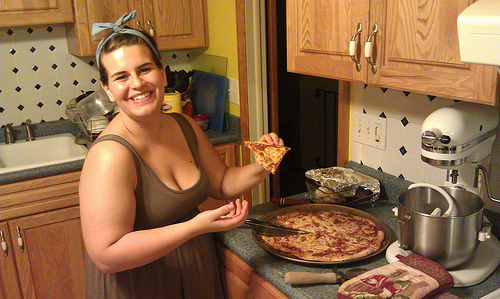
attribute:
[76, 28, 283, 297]
woman — caucasian, smiling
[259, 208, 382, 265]
pizza — cheese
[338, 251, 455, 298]
mitt — decorative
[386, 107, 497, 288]
mixer — chrome, silver, white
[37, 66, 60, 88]
tile — black, ceramic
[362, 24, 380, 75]
handle — white, silver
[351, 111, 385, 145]
outlet — white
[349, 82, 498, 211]
wall — white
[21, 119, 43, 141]
fuacet — silver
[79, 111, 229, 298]
dress — brown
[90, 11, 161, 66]
headband — grey, blue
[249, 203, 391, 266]
pan — round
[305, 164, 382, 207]
foil — tin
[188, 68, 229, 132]
board — cutting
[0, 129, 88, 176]
sink — white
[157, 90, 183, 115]
container — yellow